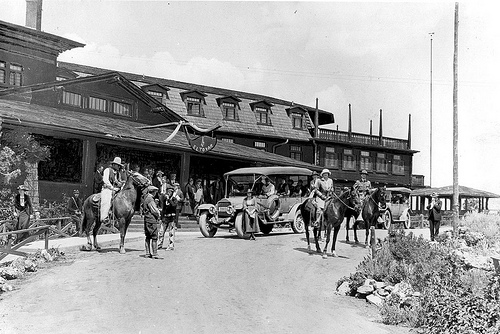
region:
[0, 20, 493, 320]
the picture is black and white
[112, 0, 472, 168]
the sky is overcast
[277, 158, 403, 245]
two horses standing together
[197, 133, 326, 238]
the car is parked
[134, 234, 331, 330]
the road is made of dirt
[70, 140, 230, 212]
people are standing around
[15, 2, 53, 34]
a chimney on top of the building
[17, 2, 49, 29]
the chimney is made of bricks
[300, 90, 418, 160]
a terrace on top of the building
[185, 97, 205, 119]
window on an old looking building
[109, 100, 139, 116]
window on an old looking building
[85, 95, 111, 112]
window on an old looking building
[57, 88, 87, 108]
window on an old looking building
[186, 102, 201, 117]
window on an old looking building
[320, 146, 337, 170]
window on an old looking building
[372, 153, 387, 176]
window on an old looking building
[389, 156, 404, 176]
window on an old looking building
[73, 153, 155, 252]
person sitting on a horse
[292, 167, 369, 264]
person sitting on a horse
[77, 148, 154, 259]
The man is riding a horse.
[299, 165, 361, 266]
The lady is riding a horse.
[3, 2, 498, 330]
The picture was taken in black and white.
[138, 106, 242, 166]
The sign is on the roof of the building.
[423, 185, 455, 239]
The man is blowing his nose.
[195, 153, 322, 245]
The automobile is very big.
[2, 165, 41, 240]
The woman is wearing a heavy coat.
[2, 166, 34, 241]
The woman is petting a dog.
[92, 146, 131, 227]
The man is dressed like a cowboy.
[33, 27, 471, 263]
gathering of people outside in front of a building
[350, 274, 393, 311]
small arrangement of decorative rocks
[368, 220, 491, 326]
arrangement of small bushes and shrubs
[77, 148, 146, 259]
a man riding on a horse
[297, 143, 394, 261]
Two people on horseback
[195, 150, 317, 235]
large old fashioned motor vehicle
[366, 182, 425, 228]
smaller old-fashioned motor vehicle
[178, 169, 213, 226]
group of spectators on the steps outside of the building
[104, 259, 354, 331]
empty space of the open dirt road area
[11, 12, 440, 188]
large unidenfified wooden building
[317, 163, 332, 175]
Person wearing hat on head.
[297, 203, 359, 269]
Dark horse standing near car.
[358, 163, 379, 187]
Hat on person's head.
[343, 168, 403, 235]
Person riding on horse.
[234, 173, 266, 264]
Person leaning against car.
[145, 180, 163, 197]
Cap on man's head.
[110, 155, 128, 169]
Man wearing large hat.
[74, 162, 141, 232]
Person riding on horse.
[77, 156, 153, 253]
a man riding a horse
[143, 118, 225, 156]
an old fashioned hanging wooden sign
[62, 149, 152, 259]
horse with a rider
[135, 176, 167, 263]
man in a cap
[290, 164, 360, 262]
person on a horse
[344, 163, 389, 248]
person on a horse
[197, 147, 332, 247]
people in a car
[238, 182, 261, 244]
person wearing a hat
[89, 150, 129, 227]
person wearing a hat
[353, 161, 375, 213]
person wearing a hat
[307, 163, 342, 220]
person wearing a hat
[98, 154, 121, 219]
the man is riding a horse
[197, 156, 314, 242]
the car is an antique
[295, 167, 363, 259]
the woman is riding a horse